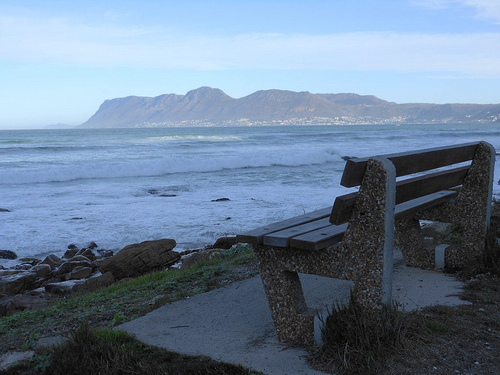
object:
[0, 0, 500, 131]
blue sky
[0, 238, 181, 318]
clump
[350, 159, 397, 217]
slat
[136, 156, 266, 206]
layers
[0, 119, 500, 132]
shore line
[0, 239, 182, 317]
rocks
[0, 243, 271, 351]
grass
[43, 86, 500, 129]
mountains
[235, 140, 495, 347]
bench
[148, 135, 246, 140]
cap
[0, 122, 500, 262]
water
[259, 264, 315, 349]
rocks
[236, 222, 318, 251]
wood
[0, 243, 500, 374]
ground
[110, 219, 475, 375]
concete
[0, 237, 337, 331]
shore